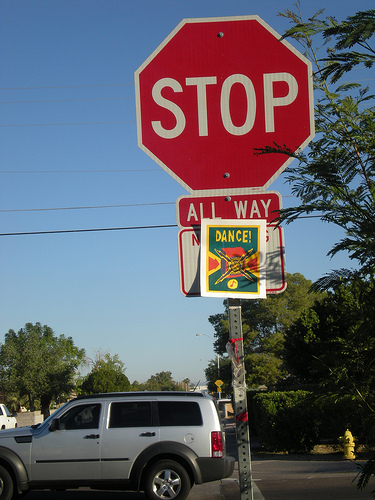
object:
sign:
[134, 14, 315, 196]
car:
[0, 380, 236, 500]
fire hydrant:
[337, 429, 358, 460]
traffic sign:
[214, 379, 223, 393]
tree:
[252, 4, 375, 494]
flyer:
[200, 217, 267, 300]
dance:
[216, 229, 252, 243]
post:
[228, 306, 254, 500]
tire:
[144, 454, 191, 500]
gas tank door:
[184, 433, 194, 443]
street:
[186, 458, 375, 500]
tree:
[0, 322, 86, 424]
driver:
[80, 406, 101, 427]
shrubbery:
[253, 390, 315, 453]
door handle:
[83, 434, 100, 440]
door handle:
[139, 432, 156, 438]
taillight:
[211, 431, 223, 458]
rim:
[152, 469, 181, 499]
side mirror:
[49, 418, 60, 431]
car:
[0, 403, 18, 432]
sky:
[0, 0, 375, 387]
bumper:
[195, 456, 235, 483]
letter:
[151, 72, 298, 139]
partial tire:
[0, 461, 18, 500]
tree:
[77, 353, 130, 395]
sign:
[175, 190, 287, 297]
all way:
[187, 198, 272, 221]